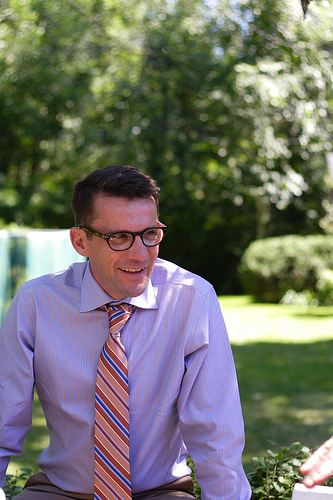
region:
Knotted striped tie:
[91, 298, 149, 467]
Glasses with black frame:
[76, 220, 173, 254]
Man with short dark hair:
[67, 164, 175, 299]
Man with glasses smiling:
[64, 163, 174, 312]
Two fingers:
[292, 420, 331, 498]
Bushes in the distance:
[237, 228, 329, 310]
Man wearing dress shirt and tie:
[38, 167, 246, 477]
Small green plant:
[252, 446, 291, 498]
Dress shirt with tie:
[41, 274, 217, 494]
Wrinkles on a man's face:
[98, 239, 120, 268]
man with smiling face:
[49, 163, 180, 330]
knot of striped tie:
[97, 299, 145, 346]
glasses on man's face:
[98, 220, 175, 260]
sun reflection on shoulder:
[158, 261, 197, 295]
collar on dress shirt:
[70, 274, 168, 318]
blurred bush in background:
[236, 231, 327, 308]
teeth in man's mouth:
[117, 263, 145, 276]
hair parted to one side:
[74, 167, 153, 206]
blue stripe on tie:
[99, 398, 126, 427]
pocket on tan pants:
[174, 469, 201, 495]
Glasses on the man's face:
[76, 220, 169, 252]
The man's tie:
[92, 301, 139, 497]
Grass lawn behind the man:
[3, 288, 331, 476]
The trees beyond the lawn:
[0, 0, 332, 291]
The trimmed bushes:
[238, 230, 332, 307]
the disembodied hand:
[296, 431, 332, 489]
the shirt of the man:
[0, 256, 253, 499]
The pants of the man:
[8, 473, 197, 499]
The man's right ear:
[67, 225, 90, 256]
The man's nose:
[128, 235, 148, 262]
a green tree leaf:
[270, 477, 281, 492]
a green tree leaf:
[253, 487, 265, 493]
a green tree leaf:
[282, 453, 295, 465]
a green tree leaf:
[252, 449, 262, 468]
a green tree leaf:
[292, 444, 304, 453]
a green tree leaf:
[17, 462, 30, 473]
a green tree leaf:
[4, 470, 14, 481]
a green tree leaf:
[5, 483, 20, 492]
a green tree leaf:
[293, 445, 312, 459]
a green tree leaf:
[250, 484, 266, 494]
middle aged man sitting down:
[10, 167, 245, 498]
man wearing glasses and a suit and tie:
[9, 168, 209, 495]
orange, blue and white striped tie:
[91, 304, 133, 496]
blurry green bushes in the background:
[235, 233, 326, 313]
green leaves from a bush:
[249, 441, 297, 482]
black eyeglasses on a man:
[71, 221, 168, 250]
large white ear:
[69, 226, 89, 257]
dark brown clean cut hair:
[71, 164, 160, 223]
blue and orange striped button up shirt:
[9, 260, 241, 498]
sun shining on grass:
[239, 310, 323, 368]